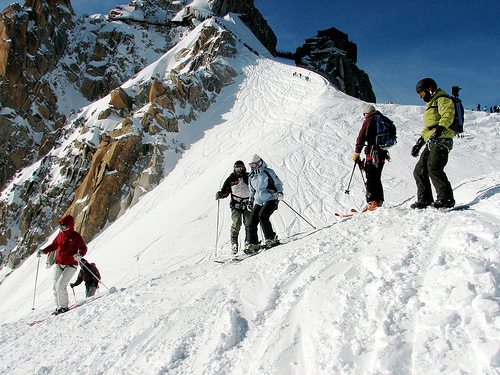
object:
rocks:
[2, 0, 233, 267]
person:
[353, 104, 398, 212]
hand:
[352, 154, 360, 163]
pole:
[344, 157, 360, 194]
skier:
[69, 258, 101, 301]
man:
[215, 160, 252, 255]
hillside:
[1, 104, 500, 373]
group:
[36, 74, 463, 316]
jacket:
[247, 162, 284, 207]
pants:
[247, 200, 278, 244]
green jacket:
[421, 87, 455, 143]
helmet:
[416, 77, 438, 93]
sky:
[256, 0, 500, 77]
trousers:
[52, 263, 76, 307]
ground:
[0, 103, 500, 375]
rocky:
[293, 26, 375, 99]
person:
[246, 154, 284, 254]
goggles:
[234, 166, 245, 171]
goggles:
[248, 160, 262, 169]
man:
[353, 104, 397, 212]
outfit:
[344, 114, 397, 194]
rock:
[293, 24, 379, 105]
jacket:
[42, 215, 88, 266]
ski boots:
[362, 201, 377, 212]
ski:
[214, 237, 286, 265]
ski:
[335, 205, 387, 218]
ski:
[27, 299, 86, 326]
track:
[293, 123, 352, 174]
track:
[203, 77, 266, 162]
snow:
[0, 0, 500, 375]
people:
[37, 215, 87, 316]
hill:
[0, 0, 500, 375]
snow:
[50, 4, 206, 101]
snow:
[234, 89, 295, 147]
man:
[410, 78, 464, 210]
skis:
[335, 209, 362, 218]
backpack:
[367, 113, 397, 150]